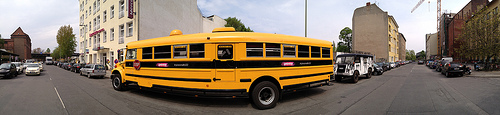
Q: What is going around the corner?
A: A bus.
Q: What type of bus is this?
A: A school bus.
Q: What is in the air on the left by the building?
A: A crane.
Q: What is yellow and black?
A: The school bus.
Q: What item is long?
A: The yellow school bus.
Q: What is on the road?
A: The school bus.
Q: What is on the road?
A: The yellow school bus.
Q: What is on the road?
A: A school bus.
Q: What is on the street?
A: A bus.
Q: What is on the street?
A: A yellow bus.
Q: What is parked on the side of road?
A: Vehicles.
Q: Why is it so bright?
A: Sunny.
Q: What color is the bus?
A: Yellos.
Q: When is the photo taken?
A: Day time.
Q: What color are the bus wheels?
A: Black.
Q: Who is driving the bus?
A: The bus driver.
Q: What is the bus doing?
A: Driving.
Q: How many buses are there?
A: One.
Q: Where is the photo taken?
A: On a street.